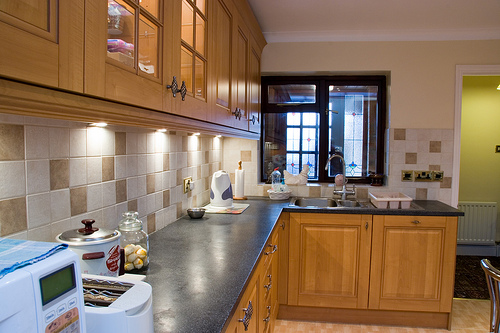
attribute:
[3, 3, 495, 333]
scene — beautiful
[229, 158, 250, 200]
paper towel holder — wooden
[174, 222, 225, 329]
counter — black, long, granite, dirty, speckled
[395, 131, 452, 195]
tiles — brown, white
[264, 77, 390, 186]
windows — pair, nice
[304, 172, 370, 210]
sink — silver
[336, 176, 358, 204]
faucet — silver, shiny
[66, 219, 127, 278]
rice cooker — red, white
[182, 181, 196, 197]
outlet — electrical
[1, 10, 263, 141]
cabinets — wood, nice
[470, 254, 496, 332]
chair — cropped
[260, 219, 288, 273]
drawer — brown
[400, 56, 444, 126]
wall — cream-colored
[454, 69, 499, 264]
door — open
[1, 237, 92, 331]
microwave — white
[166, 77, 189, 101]
knobs — metal, dark, round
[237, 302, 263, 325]
handles — metal